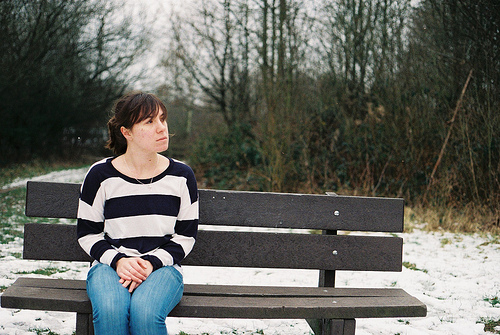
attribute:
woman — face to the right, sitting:
[114, 82, 165, 311]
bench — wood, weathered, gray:
[256, 287, 296, 309]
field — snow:
[1, 216, 12, 222]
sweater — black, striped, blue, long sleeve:
[85, 183, 189, 241]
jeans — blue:
[109, 296, 172, 308]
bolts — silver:
[328, 211, 341, 223]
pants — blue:
[160, 276, 178, 281]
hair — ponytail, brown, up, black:
[125, 99, 151, 116]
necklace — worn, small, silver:
[136, 179, 157, 187]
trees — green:
[256, 30, 316, 69]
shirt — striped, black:
[167, 170, 182, 182]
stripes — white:
[129, 207, 164, 233]